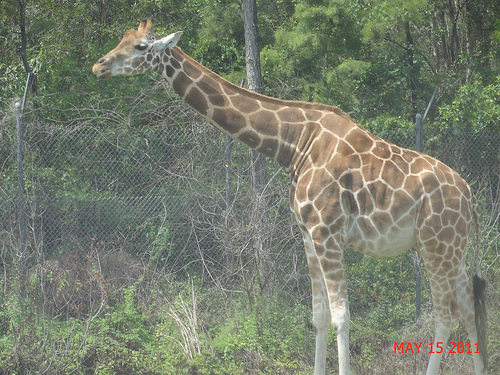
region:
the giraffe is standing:
[102, 21, 437, 300]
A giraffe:
[68, 11, 498, 366]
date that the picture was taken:
[386, 330, 490, 364]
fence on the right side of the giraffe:
[11, 9, 498, 319]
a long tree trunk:
[221, 0, 273, 309]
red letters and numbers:
[362, 321, 494, 367]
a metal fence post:
[7, 97, 52, 301]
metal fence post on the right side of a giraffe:
[399, 106, 433, 334]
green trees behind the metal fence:
[8, 2, 487, 256]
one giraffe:
[85, 9, 492, 366]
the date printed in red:
[354, 316, 498, 367]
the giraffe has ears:
[78, 23, 253, 114]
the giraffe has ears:
[97, 10, 197, 89]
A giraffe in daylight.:
[0, 15, 497, 371]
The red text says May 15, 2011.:
[382, 325, 482, 361]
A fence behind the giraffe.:
[6, 86, 492, 318]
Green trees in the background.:
[265, 11, 460, 81]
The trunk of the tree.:
[230, 6, 268, 71]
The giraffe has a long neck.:
[171, 42, 331, 172]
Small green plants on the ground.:
[55, 295, 287, 360]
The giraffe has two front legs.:
[290, 233, 365, 370]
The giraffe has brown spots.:
[312, 152, 423, 218]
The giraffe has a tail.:
[457, 191, 497, 368]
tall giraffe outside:
[89, 13, 471, 367]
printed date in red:
[381, 321, 485, 364]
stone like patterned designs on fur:
[270, 111, 460, 281]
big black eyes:
[119, 34, 159, 61]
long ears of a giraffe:
[129, 11, 216, 62]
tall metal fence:
[22, 82, 427, 359]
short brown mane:
[162, 24, 364, 124]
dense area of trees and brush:
[30, 22, 471, 351]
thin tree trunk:
[214, 6, 285, 108]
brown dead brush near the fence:
[131, 266, 231, 364]